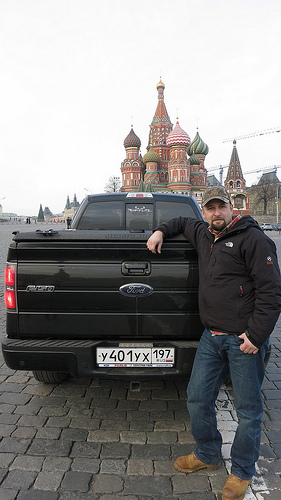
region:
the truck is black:
[3, 184, 242, 443]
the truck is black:
[39, 189, 201, 380]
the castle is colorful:
[131, 99, 236, 221]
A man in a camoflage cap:
[173, 174, 254, 255]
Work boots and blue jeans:
[179, 410, 268, 497]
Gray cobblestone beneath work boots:
[64, 419, 197, 483]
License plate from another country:
[92, 345, 178, 375]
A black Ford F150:
[26, 276, 168, 318]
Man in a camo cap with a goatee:
[195, 183, 236, 232]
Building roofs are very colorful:
[121, 71, 210, 166]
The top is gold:
[154, 73, 166, 89]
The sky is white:
[2, 32, 107, 158]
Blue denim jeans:
[196, 328, 218, 455]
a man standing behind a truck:
[145, 184, 280, 498]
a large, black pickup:
[1, 191, 271, 383]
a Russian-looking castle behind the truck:
[118, 70, 251, 217]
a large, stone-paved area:
[0, 220, 279, 498]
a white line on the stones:
[213, 381, 269, 498]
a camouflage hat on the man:
[200, 184, 230, 206]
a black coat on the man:
[152, 211, 280, 345]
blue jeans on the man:
[186, 326, 269, 480]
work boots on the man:
[173, 450, 252, 498]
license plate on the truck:
[95, 345, 176, 368]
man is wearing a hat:
[199, 182, 238, 209]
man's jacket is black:
[159, 203, 273, 334]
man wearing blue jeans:
[172, 320, 270, 480]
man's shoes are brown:
[171, 448, 254, 498]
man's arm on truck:
[133, 210, 197, 250]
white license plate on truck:
[88, 344, 181, 366]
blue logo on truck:
[108, 273, 156, 301]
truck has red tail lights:
[3, 260, 18, 314]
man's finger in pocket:
[233, 324, 245, 341]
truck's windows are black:
[81, 198, 181, 229]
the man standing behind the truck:
[144, 184, 276, 495]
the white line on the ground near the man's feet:
[204, 377, 260, 491]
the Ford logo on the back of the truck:
[115, 281, 144, 289]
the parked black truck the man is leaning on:
[0, 187, 266, 374]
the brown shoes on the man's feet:
[169, 446, 242, 490]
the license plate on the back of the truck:
[92, 342, 166, 356]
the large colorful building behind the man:
[119, 74, 249, 216]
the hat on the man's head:
[202, 186, 230, 204]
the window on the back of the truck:
[76, 200, 196, 229]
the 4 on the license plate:
[110, 349, 117, 361]